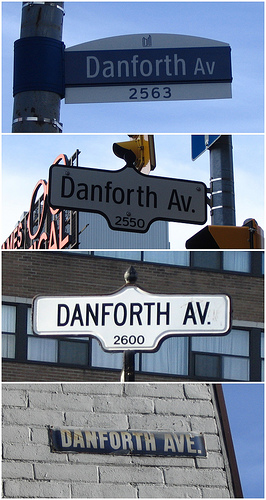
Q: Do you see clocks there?
A: No, there are no clocks.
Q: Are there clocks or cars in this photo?
A: No, there are no clocks or cars.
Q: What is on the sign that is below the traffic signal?
A: The number is on the sign.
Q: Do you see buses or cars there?
A: No, there are no cars or buses.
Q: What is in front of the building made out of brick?
A: The sign is in front of the building.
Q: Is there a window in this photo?
A: Yes, there is a window.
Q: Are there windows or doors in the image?
A: Yes, there is a window.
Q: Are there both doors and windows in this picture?
A: No, there is a window but no doors.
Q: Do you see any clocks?
A: No, there are no clocks.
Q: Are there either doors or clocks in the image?
A: No, there are no clocks or doors.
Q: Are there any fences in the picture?
A: No, there are no fences.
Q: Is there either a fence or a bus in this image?
A: No, there are no fences or buses.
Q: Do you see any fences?
A: No, there are no fences.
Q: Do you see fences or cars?
A: No, there are no fences or cars.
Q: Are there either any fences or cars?
A: No, there are no fences or cars.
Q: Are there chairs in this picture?
A: No, there are no chairs.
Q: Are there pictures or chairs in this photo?
A: No, there are no chairs or pictures.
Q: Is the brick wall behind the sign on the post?
A: Yes, the wall is behind the sign.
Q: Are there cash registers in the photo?
A: No, there are no cash registers.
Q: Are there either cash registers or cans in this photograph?
A: No, there are no cash registers or cans.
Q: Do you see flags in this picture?
A: No, there are no flags.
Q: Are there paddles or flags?
A: No, there are no flags or paddles.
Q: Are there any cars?
A: No, there are no cars.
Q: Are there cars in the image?
A: No, there are no cars.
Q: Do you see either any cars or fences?
A: No, there are no cars or fences.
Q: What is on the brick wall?
A: The sign is on the wall.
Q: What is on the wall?
A: The sign is on the wall.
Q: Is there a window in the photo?
A: Yes, there is a window.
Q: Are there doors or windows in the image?
A: Yes, there is a window.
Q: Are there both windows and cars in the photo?
A: No, there is a window but no cars.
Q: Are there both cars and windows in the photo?
A: No, there is a window but no cars.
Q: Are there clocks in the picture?
A: No, there are no clocks.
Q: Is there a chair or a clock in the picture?
A: No, there are no clocks or chairs.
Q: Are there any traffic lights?
A: Yes, there is a traffic light.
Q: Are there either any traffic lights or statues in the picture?
A: Yes, there is a traffic light.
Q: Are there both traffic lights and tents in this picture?
A: No, there is a traffic light but no tents.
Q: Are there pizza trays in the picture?
A: No, there are no pizza trays.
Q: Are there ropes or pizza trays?
A: No, there are no pizza trays or ropes.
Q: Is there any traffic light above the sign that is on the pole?
A: Yes, there is a traffic light above the sign.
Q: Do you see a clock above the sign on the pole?
A: No, there is a traffic light above the sign.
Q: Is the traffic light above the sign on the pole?
A: Yes, the traffic light is above the sign.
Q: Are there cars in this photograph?
A: No, there are no cars.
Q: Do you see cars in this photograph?
A: No, there are no cars.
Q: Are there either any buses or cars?
A: No, there are no cars or buses.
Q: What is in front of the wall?
A: The sign is in front of the wall.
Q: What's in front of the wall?
A: The sign is in front of the wall.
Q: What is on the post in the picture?
A: The sign is on the post.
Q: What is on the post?
A: The sign is on the post.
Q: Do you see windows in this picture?
A: Yes, there is a window.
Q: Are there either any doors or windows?
A: Yes, there is a window.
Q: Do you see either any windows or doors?
A: Yes, there is a window.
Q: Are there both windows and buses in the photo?
A: No, there is a window but no buses.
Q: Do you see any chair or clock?
A: No, there are no clocks or chairs.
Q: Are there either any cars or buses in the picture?
A: No, there are no cars or buses.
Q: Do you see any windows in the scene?
A: Yes, there is a window.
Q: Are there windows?
A: Yes, there is a window.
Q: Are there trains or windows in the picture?
A: Yes, there is a window.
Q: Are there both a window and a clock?
A: No, there is a window but no clocks.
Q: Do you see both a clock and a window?
A: No, there is a window but no clocks.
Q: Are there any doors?
A: No, there are no doors.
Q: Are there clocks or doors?
A: No, there are no doors or clocks.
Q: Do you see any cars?
A: No, there are no cars.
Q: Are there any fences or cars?
A: No, there are no cars or fences.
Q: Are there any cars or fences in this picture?
A: No, there are no cars or fences.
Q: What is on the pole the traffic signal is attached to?
A: The sign is on the pole.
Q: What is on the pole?
A: The sign is on the pole.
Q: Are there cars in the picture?
A: No, there are no cars.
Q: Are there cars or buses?
A: No, there are no cars or buses.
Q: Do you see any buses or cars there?
A: No, there are no cars or buses.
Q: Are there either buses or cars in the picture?
A: No, there are no cars or buses.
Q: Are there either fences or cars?
A: No, there are no cars or fences.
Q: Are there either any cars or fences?
A: No, there are no cars or fences.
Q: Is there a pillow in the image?
A: No, there are no pillows.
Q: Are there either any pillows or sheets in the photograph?
A: No, there are no pillows or sheets.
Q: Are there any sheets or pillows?
A: No, there are no pillows or sheets.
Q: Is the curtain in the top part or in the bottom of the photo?
A: The curtain is in the bottom of the image.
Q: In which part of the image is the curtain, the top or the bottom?
A: The curtain is in the bottom of the image.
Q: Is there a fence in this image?
A: No, there are no fences.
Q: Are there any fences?
A: No, there are no fences.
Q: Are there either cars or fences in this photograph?
A: No, there are no fences or cars.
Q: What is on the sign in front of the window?
A: The number is on the sign.